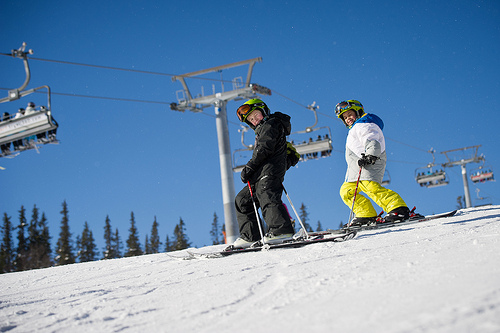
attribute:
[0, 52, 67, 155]
chairs — silver